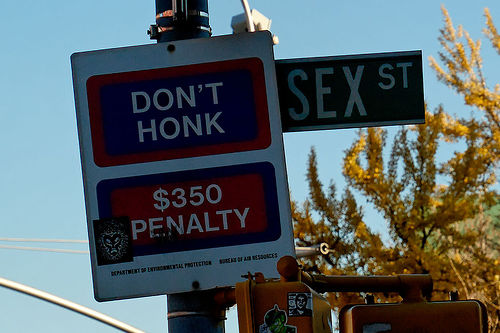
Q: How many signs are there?
A: Two.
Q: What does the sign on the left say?
A: Sex st.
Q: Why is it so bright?
A: Sunny.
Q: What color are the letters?
A: White.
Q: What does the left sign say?
A: Dont Honk.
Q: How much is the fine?
A: Three hundred fifty dollars.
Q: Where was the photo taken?
A: On sex street.